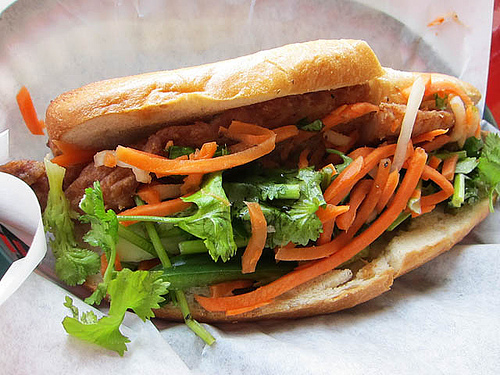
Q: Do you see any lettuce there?
A: Yes, there is lettuce.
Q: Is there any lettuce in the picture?
A: Yes, there is lettuce.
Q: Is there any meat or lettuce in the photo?
A: Yes, there is lettuce.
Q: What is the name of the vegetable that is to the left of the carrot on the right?
A: The vegetable is lettuce.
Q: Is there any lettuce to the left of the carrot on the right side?
A: Yes, there is lettuce to the left of the carrot.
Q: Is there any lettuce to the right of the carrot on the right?
A: No, the lettuce is to the left of the carrot.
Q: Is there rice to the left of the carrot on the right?
A: No, there is lettuce to the left of the carrot.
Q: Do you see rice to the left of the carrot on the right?
A: No, there is lettuce to the left of the carrot.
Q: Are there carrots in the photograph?
A: Yes, there is a carrot.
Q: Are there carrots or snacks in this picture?
A: Yes, there is a carrot.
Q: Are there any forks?
A: No, there are no forks.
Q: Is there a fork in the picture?
A: No, there are no forks.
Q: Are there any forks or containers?
A: No, there are no forks or containers.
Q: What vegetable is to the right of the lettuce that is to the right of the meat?
A: The vegetable is a carrot.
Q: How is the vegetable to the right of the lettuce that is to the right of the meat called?
A: The vegetable is a carrot.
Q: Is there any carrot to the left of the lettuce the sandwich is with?
A: No, the carrot is to the right of the lettuce.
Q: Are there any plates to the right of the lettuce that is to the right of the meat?
A: No, there is a carrot to the right of the lettuce.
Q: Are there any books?
A: No, there are no books.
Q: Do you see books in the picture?
A: No, there are no books.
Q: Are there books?
A: No, there are no books.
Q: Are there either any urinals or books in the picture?
A: No, there are no books or urinals.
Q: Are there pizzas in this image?
A: No, there are no pizzas.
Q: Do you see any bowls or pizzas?
A: No, there are no pizzas or bowls.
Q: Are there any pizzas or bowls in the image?
A: No, there are no pizzas or bowls.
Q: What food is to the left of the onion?
A: The food is a bun.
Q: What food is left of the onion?
A: The food is a bun.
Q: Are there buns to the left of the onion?
A: Yes, there is a bun to the left of the onion.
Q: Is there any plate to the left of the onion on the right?
A: No, there is a bun to the left of the onion.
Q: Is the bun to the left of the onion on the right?
A: Yes, the bun is to the left of the onion.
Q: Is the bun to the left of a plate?
A: No, the bun is to the left of the onion.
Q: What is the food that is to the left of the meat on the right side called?
A: The food is a bun.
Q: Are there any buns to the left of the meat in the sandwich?
A: Yes, there is a bun to the left of the meat.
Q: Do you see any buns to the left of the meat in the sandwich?
A: Yes, there is a bun to the left of the meat.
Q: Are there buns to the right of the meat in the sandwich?
A: No, the bun is to the left of the meat.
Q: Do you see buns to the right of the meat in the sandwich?
A: No, the bun is to the left of the meat.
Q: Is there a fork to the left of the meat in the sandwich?
A: No, there is a bun to the left of the meat.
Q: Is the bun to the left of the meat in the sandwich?
A: Yes, the bun is to the left of the meat.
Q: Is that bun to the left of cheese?
A: No, the bun is to the left of the meat.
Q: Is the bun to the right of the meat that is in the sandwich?
A: No, the bun is to the left of the meat.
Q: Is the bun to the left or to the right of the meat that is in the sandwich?
A: The bun is to the left of the meat.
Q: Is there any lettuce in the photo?
A: Yes, there is lettuce.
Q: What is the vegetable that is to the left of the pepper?
A: The vegetable is lettuce.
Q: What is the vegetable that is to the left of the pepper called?
A: The vegetable is lettuce.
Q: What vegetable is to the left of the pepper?
A: The vegetable is lettuce.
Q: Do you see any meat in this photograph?
A: Yes, there is meat.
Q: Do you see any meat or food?
A: Yes, there is meat.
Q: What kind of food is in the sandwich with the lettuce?
A: The food is meat.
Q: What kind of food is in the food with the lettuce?
A: The food is meat.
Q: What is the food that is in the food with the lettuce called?
A: The food is meat.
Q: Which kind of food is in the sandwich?
A: The food is meat.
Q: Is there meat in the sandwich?
A: Yes, there is meat in the sandwich.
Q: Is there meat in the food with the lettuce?
A: Yes, there is meat in the sandwich.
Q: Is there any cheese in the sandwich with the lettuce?
A: No, there is meat in the sandwich.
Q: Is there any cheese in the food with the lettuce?
A: No, there is meat in the sandwich.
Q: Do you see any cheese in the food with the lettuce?
A: No, there is meat in the sandwich.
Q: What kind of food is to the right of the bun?
A: The food is meat.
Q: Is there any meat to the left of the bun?
A: No, the meat is to the right of the bun.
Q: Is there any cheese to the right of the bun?
A: No, there is meat to the right of the bun.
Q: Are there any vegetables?
A: Yes, there are vegetables.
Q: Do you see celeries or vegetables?
A: Yes, there are vegetables.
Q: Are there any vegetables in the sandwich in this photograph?
A: Yes, there are vegetables in the sandwich.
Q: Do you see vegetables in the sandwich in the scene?
A: Yes, there are vegetables in the sandwich.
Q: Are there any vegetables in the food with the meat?
A: Yes, there are vegetables in the sandwich.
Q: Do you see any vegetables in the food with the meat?
A: Yes, there are vegetables in the sandwich.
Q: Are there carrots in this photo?
A: Yes, there is a carrot.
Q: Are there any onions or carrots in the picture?
A: Yes, there is a carrot.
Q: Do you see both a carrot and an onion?
A: Yes, there are both a carrot and an onion.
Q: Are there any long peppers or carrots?
A: Yes, there is a long carrot.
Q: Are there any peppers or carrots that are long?
A: Yes, the carrot is long.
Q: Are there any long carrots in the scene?
A: Yes, there is a long carrot.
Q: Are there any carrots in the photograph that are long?
A: Yes, there is a carrot that is long.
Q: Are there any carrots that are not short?
A: Yes, there is a long carrot.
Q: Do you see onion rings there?
A: No, there are no onion rings.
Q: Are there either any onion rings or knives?
A: No, there are no onion rings or knives.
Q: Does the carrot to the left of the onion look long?
A: Yes, the carrot is long.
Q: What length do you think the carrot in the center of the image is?
A: The carrot is long.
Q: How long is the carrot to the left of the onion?
A: The carrot is long.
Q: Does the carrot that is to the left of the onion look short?
A: No, the carrot is long.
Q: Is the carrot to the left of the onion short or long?
A: The carrot is long.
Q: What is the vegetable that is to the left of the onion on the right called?
A: The vegetable is a carrot.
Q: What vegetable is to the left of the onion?
A: The vegetable is a carrot.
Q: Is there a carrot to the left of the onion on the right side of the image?
A: Yes, there is a carrot to the left of the onion.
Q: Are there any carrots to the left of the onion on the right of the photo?
A: Yes, there is a carrot to the left of the onion.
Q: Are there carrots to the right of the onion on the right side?
A: No, the carrot is to the left of the onion.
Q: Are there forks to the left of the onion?
A: No, there is a carrot to the left of the onion.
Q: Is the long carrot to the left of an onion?
A: Yes, the carrot is to the left of an onion.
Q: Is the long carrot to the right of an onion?
A: No, the carrot is to the left of an onion.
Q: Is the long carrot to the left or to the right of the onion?
A: The carrot is to the left of the onion.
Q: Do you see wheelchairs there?
A: No, there are no wheelchairs.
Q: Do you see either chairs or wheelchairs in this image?
A: No, there are no wheelchairs or chairs.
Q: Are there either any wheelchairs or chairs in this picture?
A: No, there are no wheelchairs or chairs.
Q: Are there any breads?
A: Yes, there is a bread.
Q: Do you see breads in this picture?
A: Yes, there is a bread.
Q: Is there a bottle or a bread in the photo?
A: Yes, there is a bread.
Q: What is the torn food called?
A: The food is a bread.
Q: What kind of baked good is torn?
A: The baked good is a bread.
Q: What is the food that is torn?
A: The food is a bread.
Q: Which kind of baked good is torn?
A: The baked good is a bread.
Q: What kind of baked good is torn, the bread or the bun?
A: The bread is torn.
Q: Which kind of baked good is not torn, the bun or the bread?
A: The bun is not torn.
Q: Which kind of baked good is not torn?
A: The baked good is a bun.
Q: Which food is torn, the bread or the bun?
A: The bread is torn.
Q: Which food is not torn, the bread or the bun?
A: The bun is not torn.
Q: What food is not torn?
A: The food is a bun.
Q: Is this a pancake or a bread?
A: This is a bread.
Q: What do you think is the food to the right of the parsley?
A: The food is a bread.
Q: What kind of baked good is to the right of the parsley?
A: The food is a bread.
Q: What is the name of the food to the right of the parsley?
A: The food is a bread.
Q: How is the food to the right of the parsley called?
A: The food is a bread.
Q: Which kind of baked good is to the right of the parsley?
A: The food is a bread.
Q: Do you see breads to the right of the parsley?
A: Yes, there is a bread to the right of the parsley.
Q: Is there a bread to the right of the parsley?
A: Yes, there is a bread to the right of the parsley.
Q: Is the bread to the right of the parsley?
A: Yes, the bread is to the right of the parsley.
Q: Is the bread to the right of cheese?
A: No, the bread is to the right of the parsley.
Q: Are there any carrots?
A: Yes, there is a carrot.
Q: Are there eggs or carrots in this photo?
A: Yes, there is a carrot.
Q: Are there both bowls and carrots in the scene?
A: No, there is a carrot but no bowls.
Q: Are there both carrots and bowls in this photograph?
A: No, there is a carrot but no bowls.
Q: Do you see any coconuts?
A: No, there are no coconuts.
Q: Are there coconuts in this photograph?
A: No, there are no coconuts.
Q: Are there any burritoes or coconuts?
A: No, there are no coconuts or burritoes.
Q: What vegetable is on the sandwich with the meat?
A: The vegetable is a carrot.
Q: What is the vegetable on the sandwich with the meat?
A: The vegetable is a carrot.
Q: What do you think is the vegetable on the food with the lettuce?
A: The vegetable is a carrot.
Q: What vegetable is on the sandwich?
A: The vegetable is a carrot.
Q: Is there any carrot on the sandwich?
A: Yes, there is a carrot on the sandwich.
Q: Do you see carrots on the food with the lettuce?
A: Yes, there is a carrot on the sandwich.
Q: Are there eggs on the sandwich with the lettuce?
A: No, there is a carrot on the sandwich.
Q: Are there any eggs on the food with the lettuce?
A: No, there is a carrot on the sandwich.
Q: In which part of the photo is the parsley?
A: The parsley is on the left of the image.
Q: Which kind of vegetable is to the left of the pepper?
A: The vegetable is parsley.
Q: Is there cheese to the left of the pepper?
A: No, there is parsley to the left of the pepper.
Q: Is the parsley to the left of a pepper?
A: Yes, the parsley is to the left of a pepper.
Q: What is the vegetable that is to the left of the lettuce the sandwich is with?
A: The vegetable is parsley.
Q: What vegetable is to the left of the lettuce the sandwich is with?
A: The vegetable is parsley.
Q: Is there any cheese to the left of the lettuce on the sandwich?
A: No, there is parsley to the left of the lettuce.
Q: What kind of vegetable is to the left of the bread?
A: The vegetable is parsley.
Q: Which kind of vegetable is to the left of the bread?
A: The vegetable is parsley.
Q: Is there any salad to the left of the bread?
A: No, there is parsley to the left of the bread.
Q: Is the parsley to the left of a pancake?
A: No, the parsley is to the left of the bread.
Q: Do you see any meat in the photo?
A: Yes, there is meat.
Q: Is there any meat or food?
A: Yes, there is meat.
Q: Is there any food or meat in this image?
A: Yes, there is meat.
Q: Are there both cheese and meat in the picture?
A: No, there is meat but no cheese.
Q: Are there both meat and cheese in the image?
A: No, there is meat but no cheese.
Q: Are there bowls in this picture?
A: No, there are no bowls.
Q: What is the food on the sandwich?
A: The food is meat.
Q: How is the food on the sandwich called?
A: The food is meat.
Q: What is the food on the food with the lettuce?
A: The food is meat.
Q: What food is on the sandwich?
A: The food is meat.